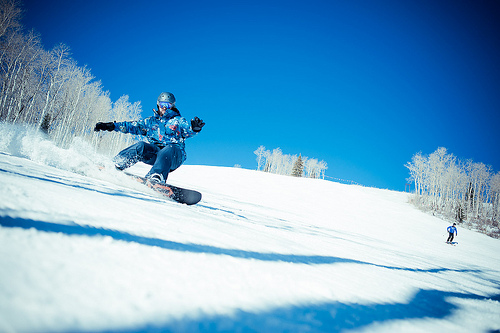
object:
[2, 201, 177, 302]
ground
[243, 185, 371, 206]
snow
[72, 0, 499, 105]
sky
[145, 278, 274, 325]
snow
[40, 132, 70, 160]
snow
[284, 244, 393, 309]
snow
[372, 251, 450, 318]
ground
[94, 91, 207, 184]
person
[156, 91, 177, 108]
helmet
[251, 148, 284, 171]
tree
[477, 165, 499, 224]
tree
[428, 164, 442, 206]
tree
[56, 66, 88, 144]
tree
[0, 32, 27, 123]
tree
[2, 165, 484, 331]
slope